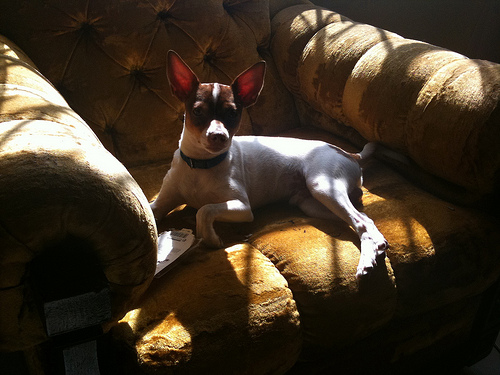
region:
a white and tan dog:
[157, 59, 403, 279]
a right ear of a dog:
[161, 43, 198, 113]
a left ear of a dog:
[236, 56, 269, 108]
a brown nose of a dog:
[206, 127, 231, 149]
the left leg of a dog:
[186, 197, 255, 253]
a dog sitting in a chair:
[4, 0, 497, 371]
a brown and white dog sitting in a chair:
[4, 0, 490, 370]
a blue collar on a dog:
[173, 147, 240, 176]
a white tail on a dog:
[353, 137, 413, 167]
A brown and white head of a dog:
[161, 52, 272, 160]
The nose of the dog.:
[210, 130, 226, 142]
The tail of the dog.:
[335, 140, 415, 165]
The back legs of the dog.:
[311, 185, 383, 275]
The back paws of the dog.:
[355, 236, 385, 281]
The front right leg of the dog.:
[192, 176, 253, 241]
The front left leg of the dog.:
[150, 180, 175, 220]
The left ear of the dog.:
[165, 50, 195, 95]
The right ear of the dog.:
[235, 58, 265, 101]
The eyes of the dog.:
[190, 104, 241, 121]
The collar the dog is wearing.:
[177, 149, 229, 170]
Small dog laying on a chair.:
[139, 53, 384, 282]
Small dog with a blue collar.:
[136, 49, 403, 280]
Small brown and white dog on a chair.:
[141, 48, 391, 273]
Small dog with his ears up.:
[148, 51, 400, 283]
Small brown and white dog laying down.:
[150, 50, 429, 280]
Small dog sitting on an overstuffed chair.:
[137, 38, 453, 303]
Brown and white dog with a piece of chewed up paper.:
[156, 48, 273, 272]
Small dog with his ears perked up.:
[156, 50, 393, 276]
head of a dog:
[148, 45, 279, 152]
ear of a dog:
[233, 50, 278, 110]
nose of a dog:
[195, 118, 257, 173]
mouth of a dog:
[188, 132, 237, 160]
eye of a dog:
[180, 97, 214, 119]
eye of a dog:
[215, 100, 245, 122]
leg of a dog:
[300, 174, 372, 252]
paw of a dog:
[200, 219, 227, 254]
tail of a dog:
[338, 137, 383, 177]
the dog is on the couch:
[150, 52, 401, 284]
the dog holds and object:
[144, 223, 192, 275]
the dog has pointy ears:
[166, 50, 265, 108]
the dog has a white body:
[149, 54, 392, 283]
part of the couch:
[6, 205, 98, 324]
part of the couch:
[25, 57, 80, 158]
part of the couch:
[251, 249, 313, 331]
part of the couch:
[418, 163, 472, 266]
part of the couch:
[393, 57, 470, 129]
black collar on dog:
[176, 150, 228, 173]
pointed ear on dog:
[230, 55, 267, 109]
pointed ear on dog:
[165, 50, 199, 100]